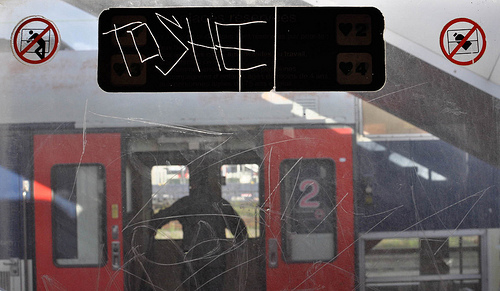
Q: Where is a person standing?
A: In the door.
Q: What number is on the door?
A: 2.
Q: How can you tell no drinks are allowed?
A: Sign on top right.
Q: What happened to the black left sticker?
A: Graffiti.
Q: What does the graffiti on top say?
A: TOSHEE.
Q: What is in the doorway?
A: A person.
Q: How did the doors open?
A: Sliding open.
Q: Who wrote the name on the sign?
A: Toshee.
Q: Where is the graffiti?
A: On the plastic.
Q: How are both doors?
A: Open.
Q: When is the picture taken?
A: Daytime.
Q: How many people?
A: One.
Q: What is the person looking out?
A: A window.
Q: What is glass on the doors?
A: Windows.